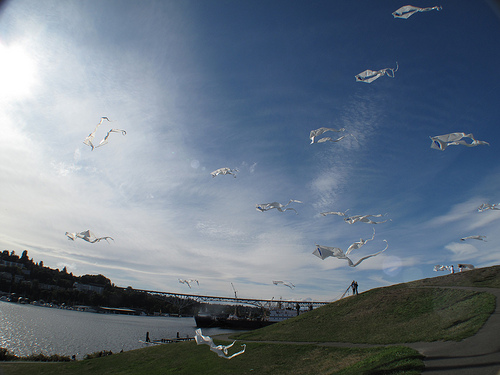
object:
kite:
[388, 2, 440, 20]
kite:
[353, 66, 399, 86]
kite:
[427, 129, 487, 153]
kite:
[253, 199, 303, 216]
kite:
[211, 165, 244, 181]